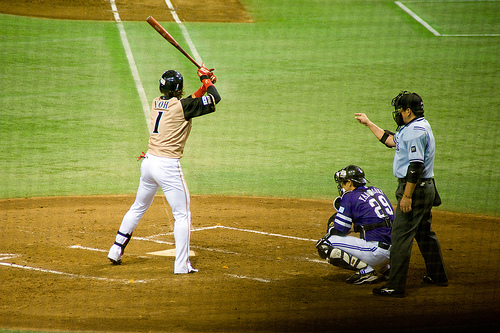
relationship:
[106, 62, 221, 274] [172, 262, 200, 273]
baseball player has foot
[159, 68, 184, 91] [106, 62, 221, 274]
helmet on baseball player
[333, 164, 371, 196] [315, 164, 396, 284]
helmet on baseball player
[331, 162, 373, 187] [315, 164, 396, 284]
helmet on baseball player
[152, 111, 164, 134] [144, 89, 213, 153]
number on back of jersey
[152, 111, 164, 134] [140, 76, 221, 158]
number on back of jersey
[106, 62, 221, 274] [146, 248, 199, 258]
baseball player at home plate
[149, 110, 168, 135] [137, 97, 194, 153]
number on baseball players back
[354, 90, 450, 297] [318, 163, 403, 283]
pitcher standing behind catcher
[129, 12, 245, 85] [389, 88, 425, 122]
bat held over head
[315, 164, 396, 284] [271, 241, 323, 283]
baseball player crouched down on brown ground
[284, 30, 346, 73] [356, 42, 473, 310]
grass in back of umpire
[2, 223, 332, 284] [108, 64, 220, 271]
lines around batter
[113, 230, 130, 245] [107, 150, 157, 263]
straps on leg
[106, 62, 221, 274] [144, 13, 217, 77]
baseball player with a red bat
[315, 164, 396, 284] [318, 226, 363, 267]
baseball player has shin guards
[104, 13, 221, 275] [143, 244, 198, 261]
baseball player standing at home plate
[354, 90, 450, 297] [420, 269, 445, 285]
pitcher wearing black shoe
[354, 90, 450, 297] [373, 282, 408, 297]
pitcher wearing black shoe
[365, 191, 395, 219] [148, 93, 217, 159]
number on jersey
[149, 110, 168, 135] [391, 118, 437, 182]
number on shirt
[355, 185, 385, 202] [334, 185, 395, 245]
surname on jersey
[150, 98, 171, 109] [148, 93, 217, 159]
surname on jersey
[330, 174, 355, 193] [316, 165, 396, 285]
mask on catcher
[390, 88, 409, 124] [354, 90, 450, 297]
mask on pitcher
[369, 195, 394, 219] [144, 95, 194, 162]
number on back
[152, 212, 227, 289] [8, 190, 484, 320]
home plate in dirt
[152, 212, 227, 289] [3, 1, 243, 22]
home plate in dirt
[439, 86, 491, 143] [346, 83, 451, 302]
ground pointing toward pitcher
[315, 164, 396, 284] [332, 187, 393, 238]
baseball player wearing jersey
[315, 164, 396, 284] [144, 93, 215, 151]
baseball player wearing jersey